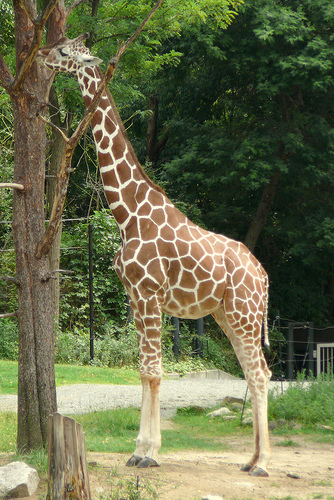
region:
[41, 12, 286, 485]
this is a giraffe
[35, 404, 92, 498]
the stump of a tree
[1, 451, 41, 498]
this is a small rock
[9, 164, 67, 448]
the bark of a tree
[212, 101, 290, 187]
this is a branch of a tree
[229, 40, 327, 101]
this is a branch of a tree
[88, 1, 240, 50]
this is a branch of a tree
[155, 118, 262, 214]
this is a branch of a tree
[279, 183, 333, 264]
this is a branch of a tree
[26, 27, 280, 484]
tall giraffe standing on dirt ground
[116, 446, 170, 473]
black giraffe hooves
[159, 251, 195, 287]
brown spots on giraffe fur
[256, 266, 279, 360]
giraffe tail with black hair at end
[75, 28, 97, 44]
ossicone on giraffe head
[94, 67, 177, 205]
brown giraffe mane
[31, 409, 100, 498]
brown tree trunk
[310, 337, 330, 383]
edge of metal fence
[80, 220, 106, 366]
black metal pole in ground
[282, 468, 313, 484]
rock on ground